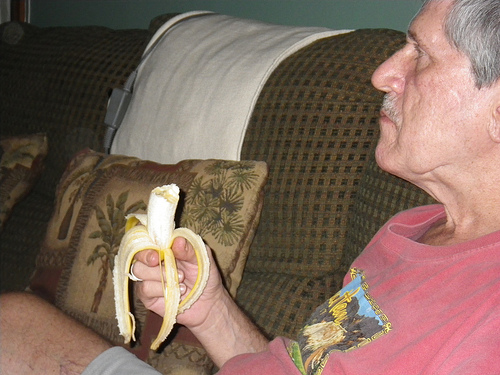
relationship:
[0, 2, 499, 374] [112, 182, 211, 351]
man holding banana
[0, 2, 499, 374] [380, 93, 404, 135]
man has facial hair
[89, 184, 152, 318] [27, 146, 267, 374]
palm tree sewn onto pillow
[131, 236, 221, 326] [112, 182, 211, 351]
hand holding banana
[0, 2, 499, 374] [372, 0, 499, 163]
man has face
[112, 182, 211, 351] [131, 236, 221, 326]
banana inside hand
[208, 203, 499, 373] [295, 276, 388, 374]
shirt has an image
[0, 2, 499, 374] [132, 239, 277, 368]
man has right arm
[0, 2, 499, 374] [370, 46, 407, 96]
man has nose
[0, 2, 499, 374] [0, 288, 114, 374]
man has bare leg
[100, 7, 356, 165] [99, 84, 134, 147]
blanket has remote control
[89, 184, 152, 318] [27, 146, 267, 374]
palm tree sewn into pillow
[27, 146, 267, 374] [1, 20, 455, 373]
pillow sitting on couch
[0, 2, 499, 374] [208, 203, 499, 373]
man wearing shirt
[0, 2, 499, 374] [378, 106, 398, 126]
man has mouth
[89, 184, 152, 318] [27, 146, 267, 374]
palm tree stitched into pillow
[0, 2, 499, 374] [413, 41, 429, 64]
man has eye